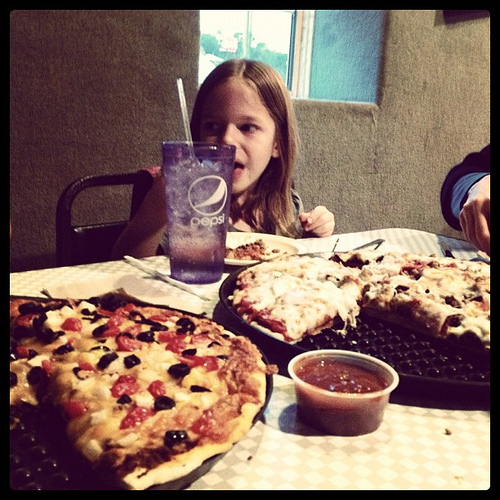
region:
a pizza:
[41, 241, 330, 488]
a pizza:
[84, 311, 168, 386]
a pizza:
[18, 279, 238, 464]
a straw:
[144, 77, 241, 164]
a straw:
[172, 71, 220, 176]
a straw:
[168, 37, 200, 154]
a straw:
[160, 78, 210, 153]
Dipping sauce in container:
[288, 337, 397, 431]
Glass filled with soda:
[166, 133, 234, 293]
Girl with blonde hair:
[203, 67, 300, 192]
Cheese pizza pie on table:
[275, 240, 473, 350]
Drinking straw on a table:
[123, 246, 219, 308]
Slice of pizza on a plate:
[231, 226, 292, 269]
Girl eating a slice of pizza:
[191, 69, 296, 192]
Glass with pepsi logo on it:
[153, 138, 236, 283]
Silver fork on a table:
[321, 230, 397, 256]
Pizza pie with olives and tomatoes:
[63, 296, 238, 438]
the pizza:
[29, 278, 291, 483]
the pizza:
[56, 247, 235, 457]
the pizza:
[62, 239, 316, 473]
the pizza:
[57, 240, 261, 495]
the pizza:
[57, 285, 267, 486]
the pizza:
[42, 277, 282, 451]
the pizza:
[55, 243, 267, 464]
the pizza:
[33, 246, 222, 443]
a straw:
[170, 87, 221, 129]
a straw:
[151, 91, 215, 225]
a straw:
[155, 54, 262, 186]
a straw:
[162, 64, 272, 232]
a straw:
[158, 84, 243, 196]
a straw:
[164, 65, 235, 182]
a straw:
[157, 58, 221, 185]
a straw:
[170, 80, 257, 244]